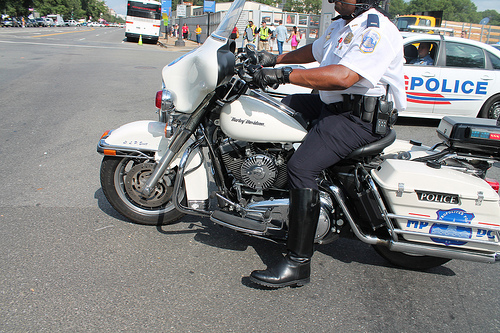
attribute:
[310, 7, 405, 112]
shirt — white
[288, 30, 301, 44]
top — pink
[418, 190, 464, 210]
lettering — white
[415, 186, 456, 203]
background — black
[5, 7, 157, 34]
cars — group, background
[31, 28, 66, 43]
line — white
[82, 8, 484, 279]
motorcycle — white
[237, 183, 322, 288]
boot — black 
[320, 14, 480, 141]
car — police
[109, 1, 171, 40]
bus — white